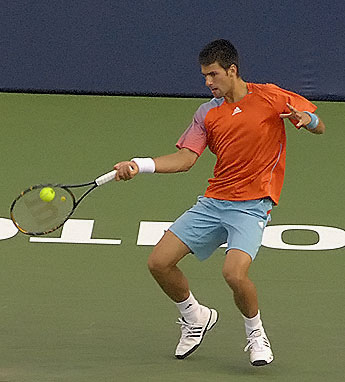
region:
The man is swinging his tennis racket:
[11, 33, 324, 359]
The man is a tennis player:
[123, 38, 317, 372]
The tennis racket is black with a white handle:
[7, 141, 139, 256]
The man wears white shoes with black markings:
[172, 306, 274, 376]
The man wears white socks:
[172, 286, 294, 339]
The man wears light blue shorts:
[165, 183, 287, 258]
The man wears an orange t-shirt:
[190, 68, 293, 205]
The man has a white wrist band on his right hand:
[124, 147, 161, 177]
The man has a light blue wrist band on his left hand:
[299, 104, 317, 136]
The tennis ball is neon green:
[38, 184, 56, 206]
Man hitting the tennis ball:
[10, 45, 324, 365]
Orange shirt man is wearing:
[176, 82, 317, 210]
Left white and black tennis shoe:
[247, 333, 274, 366]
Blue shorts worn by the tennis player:
[168, 195, 273, 263]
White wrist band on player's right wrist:
[131, 154, 154, 171]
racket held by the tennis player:
[9, 166, 134, 236]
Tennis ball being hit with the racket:
[39, 184, 54, 202]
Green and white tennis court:
[0, 93, 341, 380]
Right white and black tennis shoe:
[174, 304, 220, 360]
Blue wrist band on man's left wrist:
[301, 108, 320, 130]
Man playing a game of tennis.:
[107, 37, 296, 366]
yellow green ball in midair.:
[37, 183, 57, 203]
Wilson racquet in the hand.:
[10, 163, 130, 248]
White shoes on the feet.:
[161, 302, 272, 366]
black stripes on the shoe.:
[186, 324, 201, 340]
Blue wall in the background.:
[0, 0, 342, 102]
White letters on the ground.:
[0, 212, 342, 255]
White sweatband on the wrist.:
[126, 148, 159, 175]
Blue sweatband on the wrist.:
[301, 106, 321, 132]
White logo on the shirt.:
[227, 103, 244, 117]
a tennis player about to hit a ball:
[11, 38, 323, 368]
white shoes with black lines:
[174, 308, 273, 364]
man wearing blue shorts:
[169, 189, 272, 259]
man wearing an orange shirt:
[177, 81, 316, 203]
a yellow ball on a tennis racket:
[39, 186, 54, 202]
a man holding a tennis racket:
[10, 160, 138, 235]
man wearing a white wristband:
[132, 158, 155, 174]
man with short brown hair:
[197, 40, 239, 98]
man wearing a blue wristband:
[302, 111, 318, 130]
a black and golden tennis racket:
[10, 175, 96, 235]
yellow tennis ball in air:
[42, 187, 57, 203]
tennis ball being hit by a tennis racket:
[21, 175, 92, 249]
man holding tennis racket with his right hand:
[3, 50, 269, 242]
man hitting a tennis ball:
[12, 57, 321, 355]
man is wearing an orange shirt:
[189, 48, 306, 219]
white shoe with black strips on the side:
[236, 304, 283, 364]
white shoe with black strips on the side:
[164, 294, 216, 362]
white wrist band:
[127, 138, 160, 178]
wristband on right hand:
[127, 150, 160, 183]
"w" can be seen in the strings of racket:
[25, 189, 68, 226]